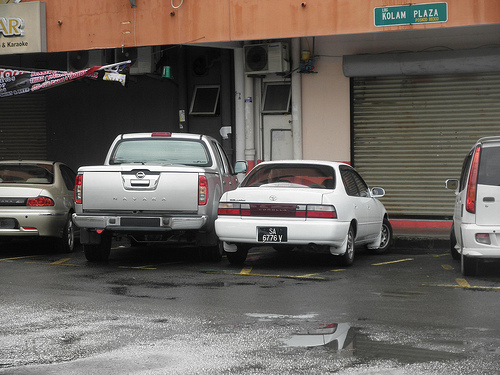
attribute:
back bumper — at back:
[213, 215, 339, 247]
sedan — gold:
[2, 160, 73, 251]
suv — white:
[446, 133, 498, 280]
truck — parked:
[70, 119, 243, 281]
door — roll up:
[335, 51, 489, 192]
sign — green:
[374, 0, 447, 28]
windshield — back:
[239, 162, 336, 187]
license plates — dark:
[259, 227, 288, 244]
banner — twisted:
[4, 37, 128, 102]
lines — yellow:
[4, 243, 486, 286]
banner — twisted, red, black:
[0, 55, 129, 104]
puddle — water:
[284, 320, 465, 370]